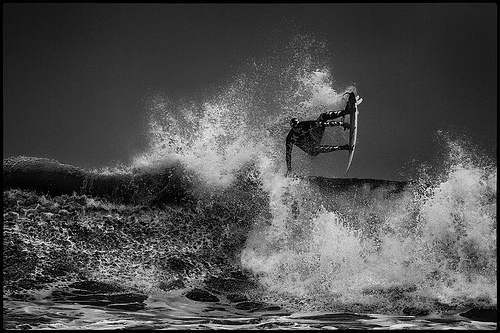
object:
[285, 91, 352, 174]
surfer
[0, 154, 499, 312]
waves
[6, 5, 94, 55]
air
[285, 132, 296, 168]
arm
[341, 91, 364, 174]
surfboard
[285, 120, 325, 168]
wet suit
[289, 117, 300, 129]
helmet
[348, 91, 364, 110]
fins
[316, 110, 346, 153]
legs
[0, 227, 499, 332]
ocean